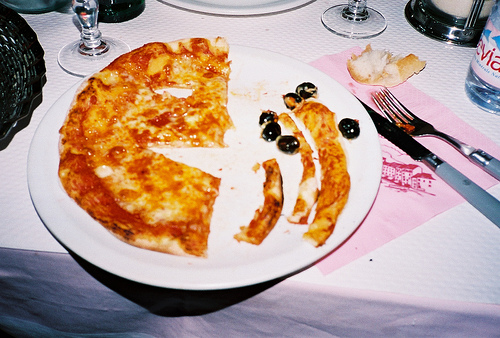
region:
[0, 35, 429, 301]
pizza on a dish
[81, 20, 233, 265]
half of pizza shaped into a pac man face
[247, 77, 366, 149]
black olives on the plate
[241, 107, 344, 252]
three pizza crusts are on the plate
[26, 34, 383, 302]
white plate is round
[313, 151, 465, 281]
pink paper napkin is under plate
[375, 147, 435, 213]
tiny dark pink graphic design of houses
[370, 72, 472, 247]
knife and fork are on top of paper napkin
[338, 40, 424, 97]
crust of bread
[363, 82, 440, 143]
top of fork has tomato sauce on it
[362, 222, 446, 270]
edge of pink napkin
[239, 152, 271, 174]
crumb droppings on white plate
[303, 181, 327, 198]
melted white gooey cheese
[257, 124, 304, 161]
shiny black olives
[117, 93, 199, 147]
several crust on pizza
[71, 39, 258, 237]
half of whole brown pizza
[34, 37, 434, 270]
large round white plate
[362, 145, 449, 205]
small house on pink napkin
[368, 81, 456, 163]
stain covered silver fork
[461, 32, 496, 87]
pink and blue label on water bottle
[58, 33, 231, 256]
Pizza on the plate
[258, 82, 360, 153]
Olives on the plate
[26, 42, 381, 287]
White paper plate on the table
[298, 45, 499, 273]
Pink napkin on the table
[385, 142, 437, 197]
Picture on the napkin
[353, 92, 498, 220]
Knife on the table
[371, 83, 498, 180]
Fork on the table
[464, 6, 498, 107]
Water bottle on the table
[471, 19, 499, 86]
Label on the water bottle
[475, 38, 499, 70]
Letters on the label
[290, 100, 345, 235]
Three Eaten Pizza crust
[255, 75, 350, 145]
Six Black olives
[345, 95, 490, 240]
Fork and Knife on table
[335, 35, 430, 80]
Piece of half eaten bread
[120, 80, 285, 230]
Cheese Pizza Pie on plate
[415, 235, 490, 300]
Clean White Tablecloth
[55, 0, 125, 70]
Stem of water glass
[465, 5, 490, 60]
Evian Water bottle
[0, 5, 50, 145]
Empty Black Bread basket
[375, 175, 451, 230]
Pink napkin with house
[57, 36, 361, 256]
a pizza that's been picked at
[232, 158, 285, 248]
the crust from a slice of pizza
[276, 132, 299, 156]
a black olive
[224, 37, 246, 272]
a white plate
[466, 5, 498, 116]
a plastic bottle of water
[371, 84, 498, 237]
a knife and fork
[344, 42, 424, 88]
a piece of a dinner roll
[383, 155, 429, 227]
a place mat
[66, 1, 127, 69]
the stem of a wineglass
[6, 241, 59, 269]
the edge of a table